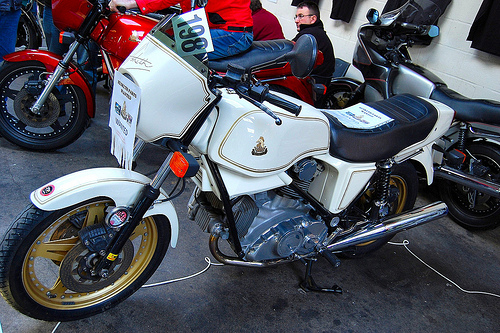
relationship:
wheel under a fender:
[15, 47, 109, 147] [25, 37, 90, 126]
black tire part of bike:
[0, 196, 173, 322] [3, 17, 451, 323]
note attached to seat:
[317, 102, 393, 131] [317, 93, 437, 165]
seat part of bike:
[317, 93, 437, 165] [3, 17, 451, 323]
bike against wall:
[362, 23, 499, 230] [260, 0, 499, 101]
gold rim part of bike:
[23, 205, 160, 305] [3, 17, 451, 323]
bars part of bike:
[141, 121, 258, 236] [18, 4, 489, 252]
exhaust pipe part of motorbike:
[208, 199, 448, 268] [0, 8, 455, 323]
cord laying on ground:
[138, 252, 225, 292] [0, 89, 498, 331]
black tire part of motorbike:
[33, 212, 139, 294] [0, 8, 455, 323]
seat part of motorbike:
[317, 93, 437, 165] [0, 8, 455, 323]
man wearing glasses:
[288, 6, 350, 68] [289, 10, 307, 20]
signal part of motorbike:
[166, 149, 201, 181] [0, 8, 455, 323]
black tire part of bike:
[0, 196, 173, 322] [3, 7, 455, 323]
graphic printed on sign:
[112, 101, 134, 126] [106, 69, 142, 170]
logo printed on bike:
[247, 137, 284, 161] [3, 7, 455, 323]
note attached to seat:
[317, 102, 393, 131] [342, 86, 499, 173]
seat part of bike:
[342, 86, 499, 173] [3, 7, 455, 323]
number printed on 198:
[177, 12, 214, 54] [175, 15, 207, 52]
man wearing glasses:
[288, 0, 336, 82] [292, 11, 312, 20]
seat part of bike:
[317, 93, 437, 165] [3, 7, 455, 323]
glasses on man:
[284, 2, 335, 94] [282, 1, 344, 73]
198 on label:
[175, 15, 207, 52] [166, 3, 220, 60]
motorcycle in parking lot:
[2, 1, 322, 155] [10, 0, 492, 330]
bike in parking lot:
[326, 0, 500, 232] [10, 0, 492, 330]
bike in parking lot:
[3, 7, 455, 323] [10, 0, 492, 330]